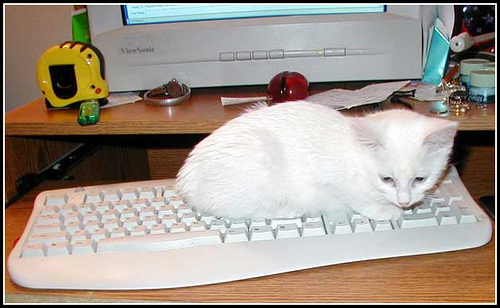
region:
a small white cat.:
[173, 92, 458, 217]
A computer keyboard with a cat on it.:
[8, 162, 490, 305]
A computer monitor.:
[85, 1, 433, 92]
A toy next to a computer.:
[36, 33, 111, 122]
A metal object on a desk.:
[133, 71, 195, 115]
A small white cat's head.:
[346, 106, 463, 203]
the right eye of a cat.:
[378, 171, 397, 196]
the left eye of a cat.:
[407, 163, 436, 193]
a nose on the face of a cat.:
[395, 171, 415, 207]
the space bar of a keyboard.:
[93, 227, 225, 254]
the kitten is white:
[178, 60, 470, 248]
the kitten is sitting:
[158, 80, 452, 224]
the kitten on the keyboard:
[164, 95, 454, 244]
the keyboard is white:
[22, 158, 243, 273]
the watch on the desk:
[138, 67, 215, 121]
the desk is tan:
[111, 112, 194, 140]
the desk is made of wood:
[117, 94, 189, 140]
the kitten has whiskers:
[368, 151, 450, 228]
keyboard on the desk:
[21, 169, 366, 286]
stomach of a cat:
[240, 140, 298, 202]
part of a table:
[374, 265, 409, 296]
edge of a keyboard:
[253, 250, 285, 273]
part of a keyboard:
[140, 235, 187, 294]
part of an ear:
[344, 111, 371, 158]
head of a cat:
[373, 123, 407, 163]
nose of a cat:
[393, 171, 405, 190]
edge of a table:
[134, 128, 174, 155]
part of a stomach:
[206, 140, 278, 191]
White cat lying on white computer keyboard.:
[171, 101, 461, 226]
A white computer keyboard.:
[3, 186, 498, 298]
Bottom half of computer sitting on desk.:
[86, 6, 466, 91]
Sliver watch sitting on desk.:
[136, 73, 202, 110]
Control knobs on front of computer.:
[208, 47, 358, 63]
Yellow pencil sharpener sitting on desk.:
[18, 37, 121, 120]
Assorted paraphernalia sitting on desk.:
[421, 31, 499, 115]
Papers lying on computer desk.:
[311, 73, 408, 116]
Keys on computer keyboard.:
[44, 192, 183, 252]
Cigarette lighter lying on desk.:
[73, 96, 105, 126]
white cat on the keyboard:
[179, 91, 450, 233]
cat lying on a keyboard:
[183, 111, 444, 221]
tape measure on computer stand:
[36, 38, 110, 107]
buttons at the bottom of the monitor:
[213, 44, 365, 69]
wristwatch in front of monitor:
[141, 75, 198, 115]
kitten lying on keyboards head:
[348, 100, 463, 229]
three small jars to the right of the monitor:
[453, 53, 498, 103]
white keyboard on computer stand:
[20, 168, 486, 283]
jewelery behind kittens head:
[423, 76, 476, 127]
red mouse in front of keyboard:
[266, 70, 320, 98]